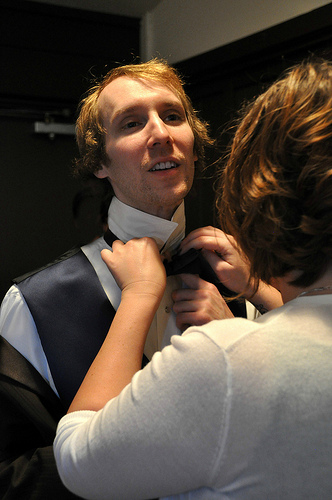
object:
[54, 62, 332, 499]
woman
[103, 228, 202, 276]
tie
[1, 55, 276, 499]
man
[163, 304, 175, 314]
button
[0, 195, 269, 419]
shirt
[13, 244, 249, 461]
vest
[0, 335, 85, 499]
jacket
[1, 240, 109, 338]
shoulder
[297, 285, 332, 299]
necklace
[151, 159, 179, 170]
teeth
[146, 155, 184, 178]
mouth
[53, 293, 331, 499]
shirt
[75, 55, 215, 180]
hair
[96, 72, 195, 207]
face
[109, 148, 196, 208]
stubble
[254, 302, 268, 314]
tattoo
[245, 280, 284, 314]
wrist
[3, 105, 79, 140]
hinge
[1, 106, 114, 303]
door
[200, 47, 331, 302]
hair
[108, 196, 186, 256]
collar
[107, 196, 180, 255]
right collar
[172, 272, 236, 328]
left hand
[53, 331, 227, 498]
left sleeve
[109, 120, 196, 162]
cheekbones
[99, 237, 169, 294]
hand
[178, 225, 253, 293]
hand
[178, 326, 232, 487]
seam